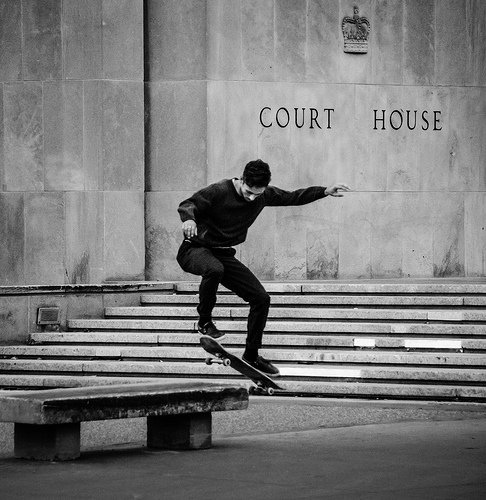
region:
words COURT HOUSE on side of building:
[256, 102, 448, 138]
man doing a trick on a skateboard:
[162, 149, 358, 412]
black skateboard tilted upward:
[199, 333, 285, 402]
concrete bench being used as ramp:
[7, 378, 253, 462]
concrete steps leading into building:
[297, 260, 485, 411]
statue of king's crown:
[339, 3, 374, 59]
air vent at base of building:
[34, 299, 65, 326]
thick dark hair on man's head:
[239, 155, 271, 206]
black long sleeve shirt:
[172, 177, 330, 256]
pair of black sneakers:
[195, 316, 288, 382]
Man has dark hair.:
[237, 162, 309, 223]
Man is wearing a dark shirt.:
[187, 212, 243, 249]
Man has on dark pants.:
[182, 231, 301, 360]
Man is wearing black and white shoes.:
[201, 300, 327, 395]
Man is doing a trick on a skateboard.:
[179, 292, 290, 416]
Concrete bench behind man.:
[89, 358, 258, 495]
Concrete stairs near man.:
[317, 243, 430, 474]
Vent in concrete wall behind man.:
[16, 271, 75, 347]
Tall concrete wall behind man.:
[82, 205, 378, 255]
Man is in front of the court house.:
[240, 41, 471, 167]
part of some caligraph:
[351, 97, 439, 148]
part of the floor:
[308, 427, 375, 484]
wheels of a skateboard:
[205, 360, 241, 372]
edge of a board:
[202, 332, 222, 348]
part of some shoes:
[257, 351, 284, 378]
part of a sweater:
[219, 206, 249, 233]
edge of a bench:
[123, 394, 182, 432]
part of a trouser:
[248, 315, 260, 344]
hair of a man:
[241, 156, 270, 194]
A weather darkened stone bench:
[38, 366, 221, 425]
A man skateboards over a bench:
[157, 300, 301, 386]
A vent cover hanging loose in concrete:
[28, 298, 85, 334]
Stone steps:
[312, 285, 462, 412]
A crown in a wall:
[321, 6, 389, 63]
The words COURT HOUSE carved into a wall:
[239, 86, 468, 154]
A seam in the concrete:
[284, 410, 441, 456]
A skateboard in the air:
[184, 320, 305, 408]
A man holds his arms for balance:
[159, 159, 367, 240]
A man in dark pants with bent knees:
[169, 235, 310, 354]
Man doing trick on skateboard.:
[200, 315, 310, 450]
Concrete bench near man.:
[44, 371, 240, 471]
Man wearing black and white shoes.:
[203, 317, 308, 414]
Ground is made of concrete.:
[97, 425, 464, 458]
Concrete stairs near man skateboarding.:
[314, 263, 475, 408]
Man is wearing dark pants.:
[171, 239, 284, 314]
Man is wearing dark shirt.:
[200, 191, 263, 252]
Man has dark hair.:
[241, 170, 278, 185]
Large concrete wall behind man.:
[50, 188, 187, 315]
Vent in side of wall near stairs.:
[42, 297, 91, 374]